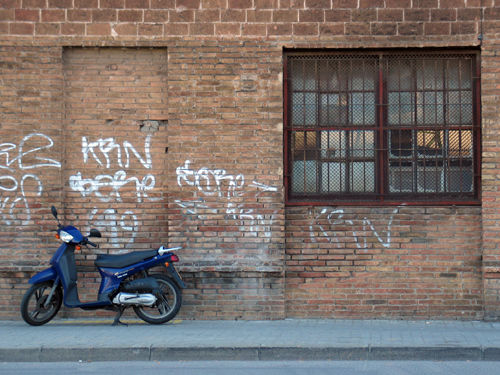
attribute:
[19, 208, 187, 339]
bike — blue, parked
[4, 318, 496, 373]
pavement — grey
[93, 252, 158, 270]
seat — black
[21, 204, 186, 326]
motorcycle — blue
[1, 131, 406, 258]
graffitti — white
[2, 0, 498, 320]
wall — brick 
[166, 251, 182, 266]
lights — red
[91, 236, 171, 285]
seat — black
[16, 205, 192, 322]
bike — blue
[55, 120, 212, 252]
writing — white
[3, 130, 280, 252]
graffiti — white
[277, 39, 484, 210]
window — missing panes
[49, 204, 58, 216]
mirror — black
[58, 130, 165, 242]
writing — white